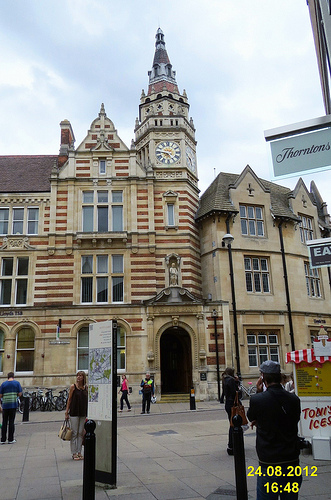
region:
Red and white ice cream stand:
[286, 332, 329, 461]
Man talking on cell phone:
[248, 359, 313, 466]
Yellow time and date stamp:
[243, 465, 321, 497]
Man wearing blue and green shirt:
[0, 366, 26, 445]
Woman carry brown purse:
[219, 365, 248, 456]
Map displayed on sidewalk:
[80, 314, 128, 492]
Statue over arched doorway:
[149, 248, 206, 405]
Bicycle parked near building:
[12, 384, 69, 415]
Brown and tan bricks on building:
[133, 248, 155, 296]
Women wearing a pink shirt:
[118, 371, 135, 412]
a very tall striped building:
[2, 33, 204, 393]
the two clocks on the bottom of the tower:
[156, 139, 196, 170]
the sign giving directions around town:
[87, 319, 113, 416]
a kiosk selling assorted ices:
[284, 339, 330, 452]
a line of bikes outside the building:
[20, 384, 69, 408]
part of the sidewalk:
[3, 418, 246, 496]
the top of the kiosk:
[287, 346, 330, 364]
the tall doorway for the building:
[157, 324, 191, 393]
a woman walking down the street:
[119, 372, 131, 414]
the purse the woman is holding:
[54, 420, 71, 440]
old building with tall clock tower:
[43, 30, 281, 410]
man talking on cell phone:
[248, 354, 312, 495]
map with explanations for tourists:
[82, 315, 116, 481]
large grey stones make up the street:
[131, 424, 218, 481]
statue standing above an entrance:
[150, 246, 191, 299]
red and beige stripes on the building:
[31, 252, 75, 307]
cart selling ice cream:
[288, 337, 329, 460]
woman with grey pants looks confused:
[47, 357, 93, 461]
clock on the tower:
[142, 132, 191, 166]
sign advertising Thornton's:
[260, 116, 325, 175]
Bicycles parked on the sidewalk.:
[30, 384, 101, 410]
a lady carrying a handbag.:
[62, 389, 80, 442]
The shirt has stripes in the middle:
[4, 369, 21, 411]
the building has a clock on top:
[145, 139, 184, 176]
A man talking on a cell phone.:
[250, 357, 303, 477]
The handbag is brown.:
[224, 393, 249, 429]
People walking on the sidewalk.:
[117, 377, 211, 417]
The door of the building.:
[157, 337, 191, 401]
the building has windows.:
[79, 189, 124, 239]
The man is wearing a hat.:
[255, 353, 289, 378]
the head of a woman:
[72, 368, 89, 385]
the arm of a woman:
[62, 383, 77, 414]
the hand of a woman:
[61, 410, 69, 419]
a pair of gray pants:
[67, 414, 87, 454]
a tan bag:
[56, 418, 75, 444]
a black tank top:
[66, 383, 89, 419]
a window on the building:
[13, 322, 40, 374]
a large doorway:
[159, 319, 196, 402]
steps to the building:
[159, 391, 194, 406]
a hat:
[258, 357, 281, 374]